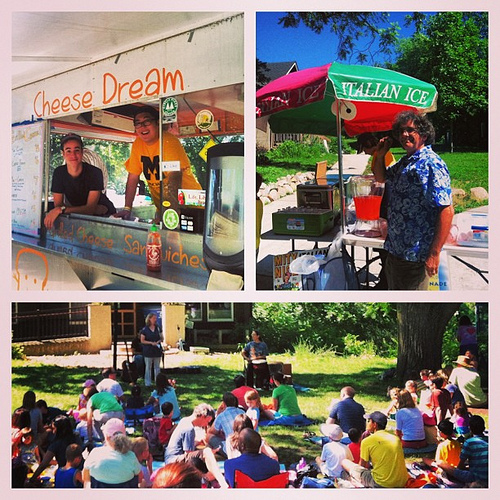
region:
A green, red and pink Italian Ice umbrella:
[253, 58, 455, 230]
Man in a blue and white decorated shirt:
[363, 111, 451, 288]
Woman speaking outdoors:
[126, 303, 181, 383]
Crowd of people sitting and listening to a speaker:
[0, 355, 498, 497]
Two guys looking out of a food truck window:
[43, 91, 210, 230]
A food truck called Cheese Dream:
[2, 4, 252, 298]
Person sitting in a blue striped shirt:
[456, 417, 491, 484]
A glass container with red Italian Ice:
[345, 177, 386, 220]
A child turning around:
[241, 390, 261, 422]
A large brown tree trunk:
[389, 303, 459, 389]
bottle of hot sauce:
[143, 220, 165, 273]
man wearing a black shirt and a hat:
[39, 124, 114, 227]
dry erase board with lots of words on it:
[0, 116, 50, 247]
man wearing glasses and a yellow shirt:
[114, 110, 206, 236]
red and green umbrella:
[244, 63, 448, 234]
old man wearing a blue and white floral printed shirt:
[352, 102, 467, 284]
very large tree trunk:
[376, 292, 470, 399]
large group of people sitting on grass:
[14, 358, 496, 484]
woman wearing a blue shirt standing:
[131, 309, 173, 385]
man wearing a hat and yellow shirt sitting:
[348, 409, 410, 495]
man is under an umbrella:
[363, 104, 458, 287]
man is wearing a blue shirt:
[374, 144, 456, 257]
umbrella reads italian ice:
[256, 51, 442, 140]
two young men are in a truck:
[29, 105, 209, 235]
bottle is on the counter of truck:
[143, 216, 169, 273]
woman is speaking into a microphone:
[132, 310, 170, 388]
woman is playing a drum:
[235, 325, 274, 391]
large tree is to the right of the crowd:
[389, 301, 455, 394]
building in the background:
[13, 302, 268, 360]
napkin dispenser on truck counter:
[196, 139, 250, 296]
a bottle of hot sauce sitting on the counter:
[130, 218, 180, 288]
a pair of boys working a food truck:
[36, 105, 196, 225]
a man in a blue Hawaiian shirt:
[360, 110, 457, 290]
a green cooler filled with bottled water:
[266, 200, 341, 237]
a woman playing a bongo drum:
[235, 325, 275, 395]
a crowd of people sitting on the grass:
[15, 361, 485, 481]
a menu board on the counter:
[10, 116, 42, 241]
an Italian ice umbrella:
[257, 59, 439, 134]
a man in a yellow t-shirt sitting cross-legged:
[340, 413, 418, 487]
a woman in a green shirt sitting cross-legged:
[259, 372, 311, 431]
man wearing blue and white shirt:
[402, 167, 447, 205]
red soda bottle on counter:
[134, 227, 174, 271]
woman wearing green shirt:
[270, 375, 305, 406]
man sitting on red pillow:
[232, 434, 296, 496]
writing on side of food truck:
[70, 221, 200, 266]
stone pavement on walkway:
[270, 175, 307, 184]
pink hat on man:
[99, 418, 142, 435]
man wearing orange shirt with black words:
[105, 141, 227, 213]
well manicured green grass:
[28, 367, 73, 381]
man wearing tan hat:
[445, 352, 477, 374]